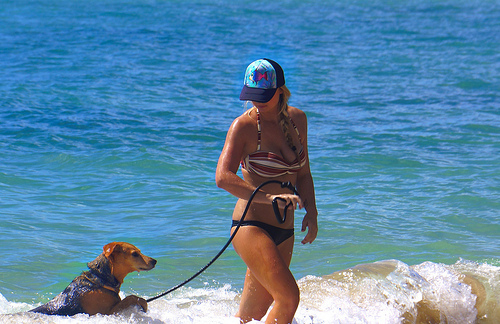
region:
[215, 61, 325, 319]
as woman in a bathing suit walking a dog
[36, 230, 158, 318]
a dog on a leash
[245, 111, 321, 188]
a red and white striped bikini top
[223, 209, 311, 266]
a black bikini bottom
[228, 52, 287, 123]
a blue hat with a pink fish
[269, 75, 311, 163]
a woman's blond hair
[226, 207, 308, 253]
a black bathing suit bottom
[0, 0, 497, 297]
a blue body of water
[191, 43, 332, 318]
woman is wearing a bikini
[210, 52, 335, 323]
woman is wearing a trucker cap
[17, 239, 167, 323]
dog is on a leash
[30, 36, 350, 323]
woman is walking a dog on the beach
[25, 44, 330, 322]
woman is walking a dog in the waves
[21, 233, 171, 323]
dog is brown and tan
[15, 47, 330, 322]
woman is holding dog's leash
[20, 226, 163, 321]
dog is walking in the surf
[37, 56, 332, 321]
woman is looking at dog on a leash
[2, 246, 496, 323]
surf is breaking at woman's feet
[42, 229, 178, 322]
dog with the woman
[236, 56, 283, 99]
hat on the woman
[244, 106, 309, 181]
swim top on the woman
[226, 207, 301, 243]
swim bottom on the woman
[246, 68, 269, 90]
image on the hat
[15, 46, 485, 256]
water behind woman and dog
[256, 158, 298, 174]
striped pattern on swim top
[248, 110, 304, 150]
straps on woman's swim top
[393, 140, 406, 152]
part of an ocean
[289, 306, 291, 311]
edge of a knee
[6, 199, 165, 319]
a dog in the ocean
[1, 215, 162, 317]
a dog swimming in the water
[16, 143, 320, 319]
a dog on a leash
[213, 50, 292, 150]
a woman wearing a hat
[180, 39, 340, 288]
a woman wearing a bikini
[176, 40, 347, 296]
a woman wearing a swim suit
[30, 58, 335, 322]
a woman walking a dog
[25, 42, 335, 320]
a woman walking a dog in the ocean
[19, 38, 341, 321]
a woman walking a dog in water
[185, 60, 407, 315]
a woman in the ocean